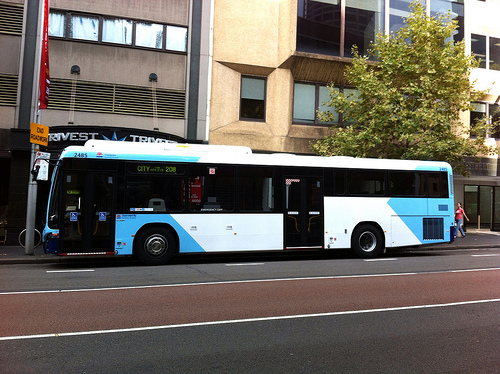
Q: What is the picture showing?
A: It is showing a street.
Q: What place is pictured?
A: It is a street.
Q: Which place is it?
A: It is a street.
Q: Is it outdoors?
A: Yes, it is outdoors.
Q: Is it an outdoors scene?
A: Yes, it is outdoors.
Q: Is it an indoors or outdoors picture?
A: It is outdoors.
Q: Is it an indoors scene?
A: No, it is outdoors.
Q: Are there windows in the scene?
A: Yes, there is a window.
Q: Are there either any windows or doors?
A: Yes, there is a window.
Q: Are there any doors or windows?
A: Yes, there is a window.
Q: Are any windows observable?
A: Yes, there is a window.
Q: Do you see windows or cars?
A: Yes, there is a window.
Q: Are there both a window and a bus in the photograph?
A: Yes, there are both a window and a bus.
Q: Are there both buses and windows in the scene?
A: Yes, there are both a window and a bus.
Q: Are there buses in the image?
A: Yes, there is a bus.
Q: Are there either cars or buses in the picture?
A: Yes, there is a bus.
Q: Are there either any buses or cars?
A: Yes, there is a bus.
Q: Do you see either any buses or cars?
A: Yes, there is a bus.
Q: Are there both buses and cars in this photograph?
A: No, there is a bus but no cars.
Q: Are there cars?
A: No, there are no cars.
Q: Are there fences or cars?
A: No, there are no cars or fences.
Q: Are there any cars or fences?
A: No, there are no cars or fences.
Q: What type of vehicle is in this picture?
A: The vehicle is a bus.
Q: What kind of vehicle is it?
A: The vehicle is a bus.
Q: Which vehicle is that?
A: This is a bus.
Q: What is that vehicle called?
A: This is a bus.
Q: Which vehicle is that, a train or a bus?
A: This is a bus.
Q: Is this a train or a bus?
A: This is a bus.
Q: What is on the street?
A: The bus is on the street.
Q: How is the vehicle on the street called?
A: The vehicle is a bus.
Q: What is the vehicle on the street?
A: The vehicle is a bus.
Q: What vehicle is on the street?
A: The vehicle is a bus.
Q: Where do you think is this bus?
A: The bus is on the street.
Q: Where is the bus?
A: The bus is on the street.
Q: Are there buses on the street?
A: Yes, there is a bus on the street.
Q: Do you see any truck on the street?
A: No, there is a bus on the street.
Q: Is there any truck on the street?
A: No, there is a bus on the street.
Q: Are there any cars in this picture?
A: No, there are no cars.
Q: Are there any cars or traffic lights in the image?
A: No, there are no cars or traffic lights.